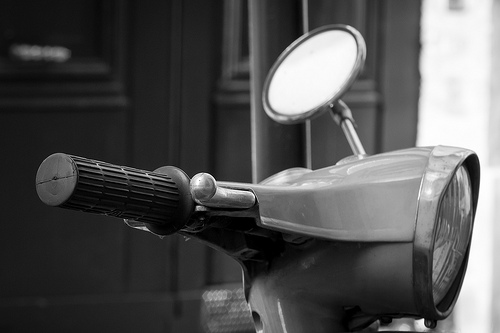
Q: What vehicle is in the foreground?
A: Motorcycle.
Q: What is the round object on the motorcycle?
A: Mirror.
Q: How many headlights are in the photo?
A: One.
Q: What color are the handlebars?
A: Black.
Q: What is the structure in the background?
A: Wall.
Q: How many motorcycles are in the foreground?
A: One.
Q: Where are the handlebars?
A: Next to the headlights.